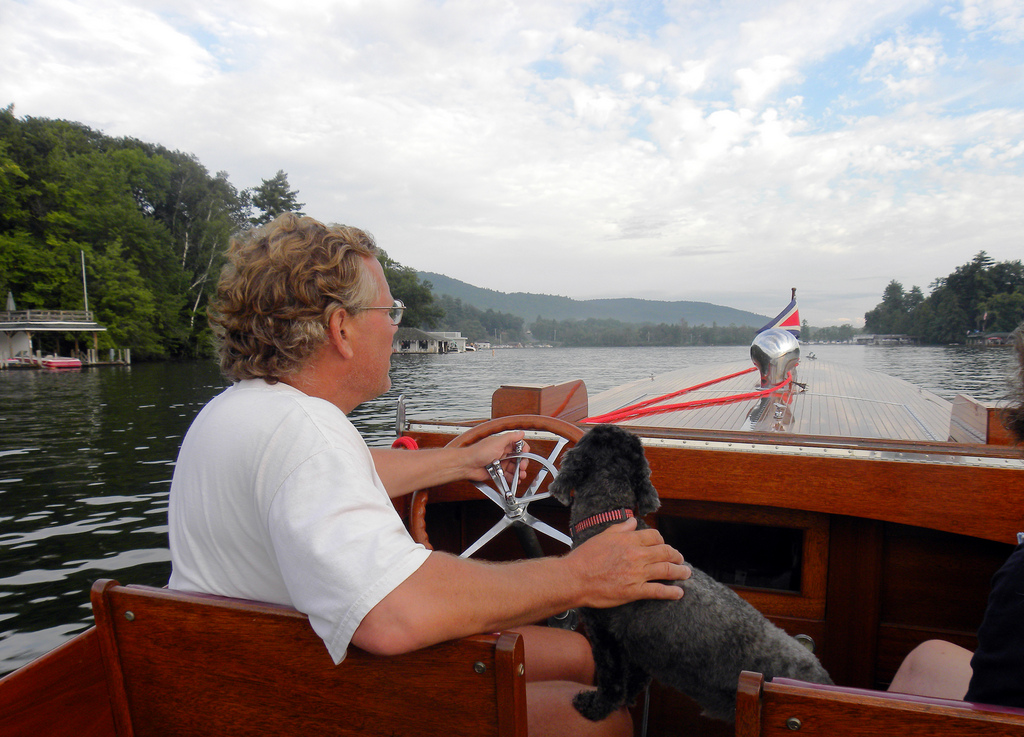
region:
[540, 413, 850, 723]
Gray dog sitting in the boat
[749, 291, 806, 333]
flag on the front of the boat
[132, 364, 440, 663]
Man wearing a white tee shirt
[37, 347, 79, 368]
Pink boat in the water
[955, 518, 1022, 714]
person wearing a black shirt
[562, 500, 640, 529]
red collar on the dog neck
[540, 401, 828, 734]
gray dog on the man lap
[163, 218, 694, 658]
A man driving a boat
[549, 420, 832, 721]
A dog in a boat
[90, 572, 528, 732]
A wood seat on a boat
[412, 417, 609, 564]
A steering wheel on a boat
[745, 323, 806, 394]
A light on a boat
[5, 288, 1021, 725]
A boat in the water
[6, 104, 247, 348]
Trees near a lake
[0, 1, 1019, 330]
White clouds in a blue sky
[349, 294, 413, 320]
Glasses on a man's face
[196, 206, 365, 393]
the hair is blonde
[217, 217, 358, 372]
the hair is curly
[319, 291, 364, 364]
the ear of the man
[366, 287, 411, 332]
the glasses are clear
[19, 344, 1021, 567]
the water is green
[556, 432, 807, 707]
a dog that is black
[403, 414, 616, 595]
steering wheel of the boat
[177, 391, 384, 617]
the shirt is white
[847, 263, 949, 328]
a group of tall trees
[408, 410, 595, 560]
Steering wheel on a boat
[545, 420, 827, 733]
A dog on a boat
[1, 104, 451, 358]
Trees beside the water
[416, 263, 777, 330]
A mountain behind the water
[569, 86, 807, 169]
White clouds in a blue sky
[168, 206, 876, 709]
man and dog on the boat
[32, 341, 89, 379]
red boat in the water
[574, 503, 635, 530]
red collar around the dogs neck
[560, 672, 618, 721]
paw of the dog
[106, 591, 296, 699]
back of the seat on the boat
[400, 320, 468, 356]
white house on the water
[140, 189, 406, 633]
glasses on the man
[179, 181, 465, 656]
man wearing a white shirt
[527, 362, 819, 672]
black dog with red collar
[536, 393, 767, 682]
black dog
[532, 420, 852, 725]
The dog is black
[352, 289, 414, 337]
The person is wearing glasses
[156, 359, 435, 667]
The person is wearing a white shirt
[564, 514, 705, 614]
The person's right hand is petting the dog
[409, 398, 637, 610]
The steering wheel is wood and white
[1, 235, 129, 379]
There is a boat house on the left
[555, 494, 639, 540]
The dog has a red collar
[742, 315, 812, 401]
There is a silver piece on the front of the boat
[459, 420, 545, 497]
The person's left hand is steering the boat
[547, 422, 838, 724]
A black and grey dog.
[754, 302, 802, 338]
A blue, red and white flag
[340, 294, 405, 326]
Glasses on a boat drivers face.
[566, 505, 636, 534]
A mostly red dog collar.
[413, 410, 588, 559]
A brown and silver steering wheel.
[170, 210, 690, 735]
Boat driver with glasses and white shirt.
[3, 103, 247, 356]
The greenest area of trees.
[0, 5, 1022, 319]
All the white clouds.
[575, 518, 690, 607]
A right hand on a dog.